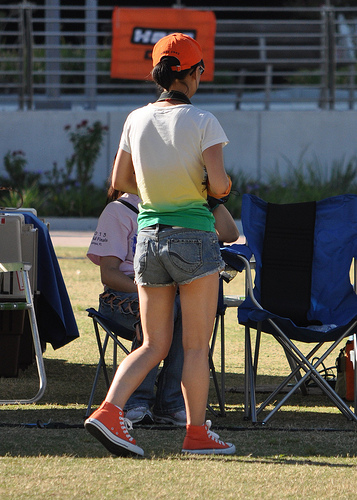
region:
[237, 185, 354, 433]
blue and black lawn chair on grass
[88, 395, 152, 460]
left orange sneaker on foot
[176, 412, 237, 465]
right orange sneaker on foot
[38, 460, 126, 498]
grass on the ground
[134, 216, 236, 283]
jean shorts on woman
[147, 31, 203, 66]
orange baseball cap on woman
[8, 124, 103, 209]
brush along the back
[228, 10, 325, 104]
metal fence along the road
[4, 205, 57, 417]
chair folded up on ground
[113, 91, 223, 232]
tan yellow and green t shirt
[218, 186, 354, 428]
a blue and black chair.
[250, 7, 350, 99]
a thin grey fence.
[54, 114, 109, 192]
a green rose bush.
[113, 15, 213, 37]
a orange and black sign.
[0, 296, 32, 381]
a dark brown cart.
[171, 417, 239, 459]
a orange and white sneaker.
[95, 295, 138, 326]
a woman is wearing blue jeans.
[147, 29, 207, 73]
a woman is wearing a orange cap.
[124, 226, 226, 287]
a woman is wearing blue jean shorts.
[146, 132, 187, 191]
a woman is wearing a white and green tea shirt.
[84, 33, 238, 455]
The back of a girl in orange shoes and hat.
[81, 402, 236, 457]
Orange and white sneakers on a woman.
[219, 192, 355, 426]
A blue chair with silver base.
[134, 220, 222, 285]
Blue jean shorts on a girl with orange shoes.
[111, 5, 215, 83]
An orange sign past the people.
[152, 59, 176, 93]
Black pony tail sticking out the back of a girls orange hat.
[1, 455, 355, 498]
Ground that the sun is shining on behind the girl's feet.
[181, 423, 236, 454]
An orange sneaker on a girl's right foot.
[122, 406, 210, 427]
Grey and black sneakers on the feet of a person past the orange shoes girl.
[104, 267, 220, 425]
Bare legs of a girl in orange sneakers and hat.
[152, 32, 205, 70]
the orange hat on the woman's head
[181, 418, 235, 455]
the orange shoe on the foot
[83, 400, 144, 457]
the orange shoe on the foot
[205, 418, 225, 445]
the white shoelaces on the shoe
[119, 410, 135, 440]
the white shoelaces on the shoe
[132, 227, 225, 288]
the blue denim shorts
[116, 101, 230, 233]
the short sleeved shirt on the woman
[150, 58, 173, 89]
the hair in the ponytail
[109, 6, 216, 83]
the orange banner hanging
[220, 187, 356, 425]
the blue empty chair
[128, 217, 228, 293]
woman's short blue jean shorts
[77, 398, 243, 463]
orange pair of converse sneakers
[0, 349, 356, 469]
shaded area in the grass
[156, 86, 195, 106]
strap around a woman's neck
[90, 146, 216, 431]
woman sitting in a chair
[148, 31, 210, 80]
woman's orange colored hat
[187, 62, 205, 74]
woman's pair of glasses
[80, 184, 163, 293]
person's pink tee shirt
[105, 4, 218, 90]
orange banner on a fence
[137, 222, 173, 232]
belt on a woman's shorts